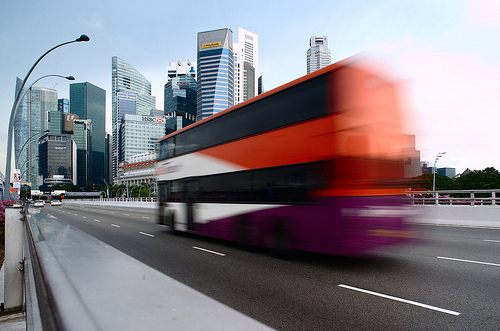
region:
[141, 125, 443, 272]
a bus driving on a street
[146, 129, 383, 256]
a bus containing two levels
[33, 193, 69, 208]
cars driving on a street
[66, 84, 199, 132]
buildings built in a city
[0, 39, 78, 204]
street lights standing near a street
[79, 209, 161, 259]
lines painted on the street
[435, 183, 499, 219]
rails built on the side of the street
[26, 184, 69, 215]
cars driving into a city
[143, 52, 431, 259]
A bus is driving past the road.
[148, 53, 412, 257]
The bus is a double decker.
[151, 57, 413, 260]
The bus is red, white and purple.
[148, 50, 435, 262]
The bus is driving very quickly.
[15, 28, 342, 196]
Some tall buildings are in the distance.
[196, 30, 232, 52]
A yellow sign is on the building.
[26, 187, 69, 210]
Some cars are in the distance.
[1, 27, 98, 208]
Some street lights are on the side.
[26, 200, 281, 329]
The sidewalk is gray.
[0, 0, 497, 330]
A bus is driving to the city.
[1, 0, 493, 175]
clear blue sky over skyline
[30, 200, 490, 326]
broken white lines dividing road lanes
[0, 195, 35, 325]
white pillar by edge of overpass and lower ground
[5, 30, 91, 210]
curved lampposts over roadway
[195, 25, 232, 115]
angled building with blue and white stripes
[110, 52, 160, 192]
building with curved roof over rectangular buildings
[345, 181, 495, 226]
low partition and railing behind bus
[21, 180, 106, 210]
overpass crossing over top of roadway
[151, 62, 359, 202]
white and red stripe between black bus windows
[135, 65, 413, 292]
this is a double decker bus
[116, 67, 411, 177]
bus has red top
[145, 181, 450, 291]
purple trim on bus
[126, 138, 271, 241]
white front of bus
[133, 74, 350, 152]
top row of windows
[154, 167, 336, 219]
bottom row of windows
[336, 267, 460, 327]
white line on street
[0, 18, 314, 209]
sky scrapers in background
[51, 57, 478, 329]
bus driving on street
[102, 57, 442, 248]
this is a bus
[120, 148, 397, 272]
purple on lower bus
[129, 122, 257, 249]
white front on bus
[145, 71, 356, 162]
upper windows on bus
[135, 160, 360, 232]
lower windows on bus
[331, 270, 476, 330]
white line on street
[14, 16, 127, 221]
a curved street light pole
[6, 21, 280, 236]
a group of sky scrapers